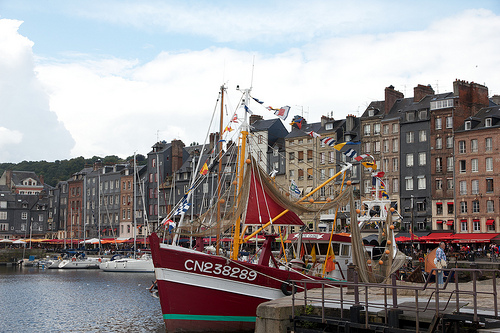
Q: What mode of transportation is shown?
A: Boat.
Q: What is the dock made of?
A: Wood.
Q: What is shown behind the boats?
A: Buildings.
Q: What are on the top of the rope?
A: Flags.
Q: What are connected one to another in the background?
A: Buildings.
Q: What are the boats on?
A: Water.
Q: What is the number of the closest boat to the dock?
A: CN238289.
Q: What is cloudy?
A: Sky.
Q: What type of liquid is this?
A: Water.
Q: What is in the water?
A: A boat.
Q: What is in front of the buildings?
A: Water.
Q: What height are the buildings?
A: Tall.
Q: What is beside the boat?
A: A pier.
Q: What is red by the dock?
A: A boat.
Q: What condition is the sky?
A: Cloudy.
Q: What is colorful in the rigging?
A: Pennants.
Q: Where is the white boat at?
A: Anogther dock.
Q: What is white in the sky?
A: Clouds.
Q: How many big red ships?
A: One.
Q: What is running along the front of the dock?
A: Metal railing.